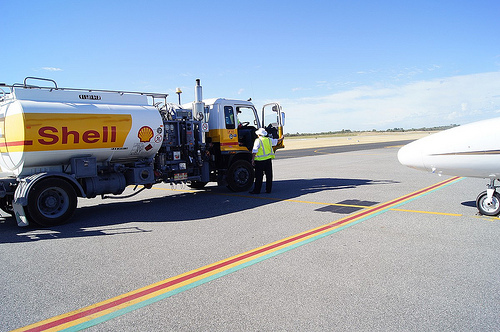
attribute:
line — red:
[257, 235, 287, 258]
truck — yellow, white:
[16, 85, 242, 199]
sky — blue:
[273, 17, 320, 51]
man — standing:
[254, 127, 278, 190]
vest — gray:
[256, 140, 271, 161]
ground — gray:
[197, 231, 217, 255]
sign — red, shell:
[9, 111, 124, 147]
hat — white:
[245, 123, 262, 139]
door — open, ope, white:
[247, 100, 287, 121]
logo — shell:
[128, 118, 162, 146]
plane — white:
[396, 119, 484, 189]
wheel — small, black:
[475, 183, 497, 215]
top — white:
[46, 91, 64, 102]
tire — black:
[25, 179, 75, 224]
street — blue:
[273, 229, 291, 250]